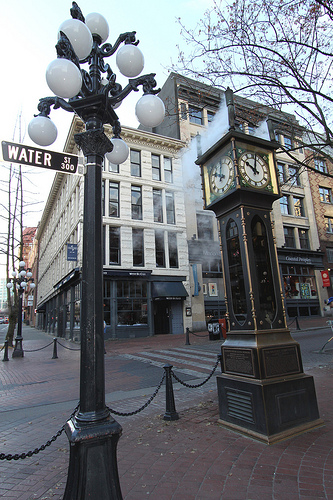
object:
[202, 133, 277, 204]
clock tower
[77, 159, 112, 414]
pole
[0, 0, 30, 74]
sky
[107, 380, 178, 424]
metal chain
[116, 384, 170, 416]
black chain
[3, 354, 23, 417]
street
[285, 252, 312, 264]
name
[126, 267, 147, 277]
name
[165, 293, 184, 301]
name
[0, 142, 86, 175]
sign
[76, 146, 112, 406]
pole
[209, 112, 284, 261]
tower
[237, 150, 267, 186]
clock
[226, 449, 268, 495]
sidewalk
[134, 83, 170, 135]
globes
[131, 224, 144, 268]
windows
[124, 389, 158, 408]
chain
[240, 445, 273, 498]
lines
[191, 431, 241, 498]
lines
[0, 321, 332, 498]
ground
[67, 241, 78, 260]
flag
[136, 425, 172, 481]
sidewalk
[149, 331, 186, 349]
doorway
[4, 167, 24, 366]
tree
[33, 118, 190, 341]
branches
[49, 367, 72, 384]
pavers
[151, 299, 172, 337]
door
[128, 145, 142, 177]
window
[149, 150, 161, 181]
window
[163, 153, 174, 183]
window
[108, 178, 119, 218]
window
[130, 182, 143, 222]
window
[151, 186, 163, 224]
window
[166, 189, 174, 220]
window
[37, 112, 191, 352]
building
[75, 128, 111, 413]
post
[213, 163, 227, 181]
hands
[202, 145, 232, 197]
clock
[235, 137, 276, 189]
clock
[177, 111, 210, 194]
steam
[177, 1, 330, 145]
tree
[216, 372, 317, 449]
base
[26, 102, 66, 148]
light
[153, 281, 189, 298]
awning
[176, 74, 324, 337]
branches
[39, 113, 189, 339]
building